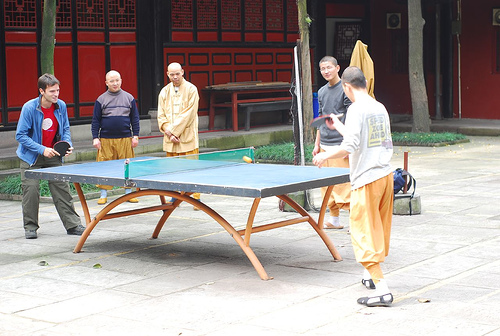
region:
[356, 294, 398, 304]
sandles on a man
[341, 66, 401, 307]
man playing a ping pong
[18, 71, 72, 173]
man playing a ping pong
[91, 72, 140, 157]
shjort man watching game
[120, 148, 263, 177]
green table tennis net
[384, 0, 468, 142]
tree with a grass bottom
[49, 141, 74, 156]
red and black tennis paddle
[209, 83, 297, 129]
red an black table and bench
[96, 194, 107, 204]
yellow sandles on a man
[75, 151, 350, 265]
table tennis playing surface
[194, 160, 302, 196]
a tennis table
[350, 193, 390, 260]
orange shorts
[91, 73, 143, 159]
a man standing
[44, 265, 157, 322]
the ground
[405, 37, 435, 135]
a tree trunk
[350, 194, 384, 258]
man wearing shorts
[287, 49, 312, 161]
a pole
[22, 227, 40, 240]
a shoe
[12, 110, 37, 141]
a blue jacket the man is wearing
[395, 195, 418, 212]
bag on the ground is grey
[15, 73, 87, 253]
THIS IS A MAN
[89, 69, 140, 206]
THIS IS A MAN WITH A BALD HEAD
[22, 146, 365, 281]
THIS IS A PING PONG TABLE?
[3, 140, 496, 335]
THIS IS A FLOOR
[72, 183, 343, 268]
THESE ARE LEGS ON THE TABLE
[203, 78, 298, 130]
THIS IS A BENCH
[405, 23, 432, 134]
THIS IS A TREE?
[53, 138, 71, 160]
THIS IS A PADDLE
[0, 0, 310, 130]
THE WALL IS RED AND BLACK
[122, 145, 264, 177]
THIS IS A NET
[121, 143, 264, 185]
table tennis net with an orange ball moving near it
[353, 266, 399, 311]
men's Asian footwear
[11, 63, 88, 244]
man wearing a jacket and holding a ping pong paddle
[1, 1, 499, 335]
men playing and watching table tennis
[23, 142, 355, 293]
outdoor ping pong table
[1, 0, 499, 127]
Asian architecture with red walls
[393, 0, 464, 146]
grayish tree trunk with grass at the base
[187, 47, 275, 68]
design with black outlined rectangles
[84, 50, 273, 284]
two Asian men watching ping pong being played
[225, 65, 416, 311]
man playing table tennis seen from behind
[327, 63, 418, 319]
Man wearing a gray shirt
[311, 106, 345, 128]
Paddle in the man's hand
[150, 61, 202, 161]
Man looking at table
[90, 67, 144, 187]
Man wearing gold shorts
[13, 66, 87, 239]
Man wearing a blue jacket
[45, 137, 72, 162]
Paddle in the man's hand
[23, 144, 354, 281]
Table in between the men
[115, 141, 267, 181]
Net on the table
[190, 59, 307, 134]
Table in the background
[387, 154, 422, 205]
Blue bookbag on the ground